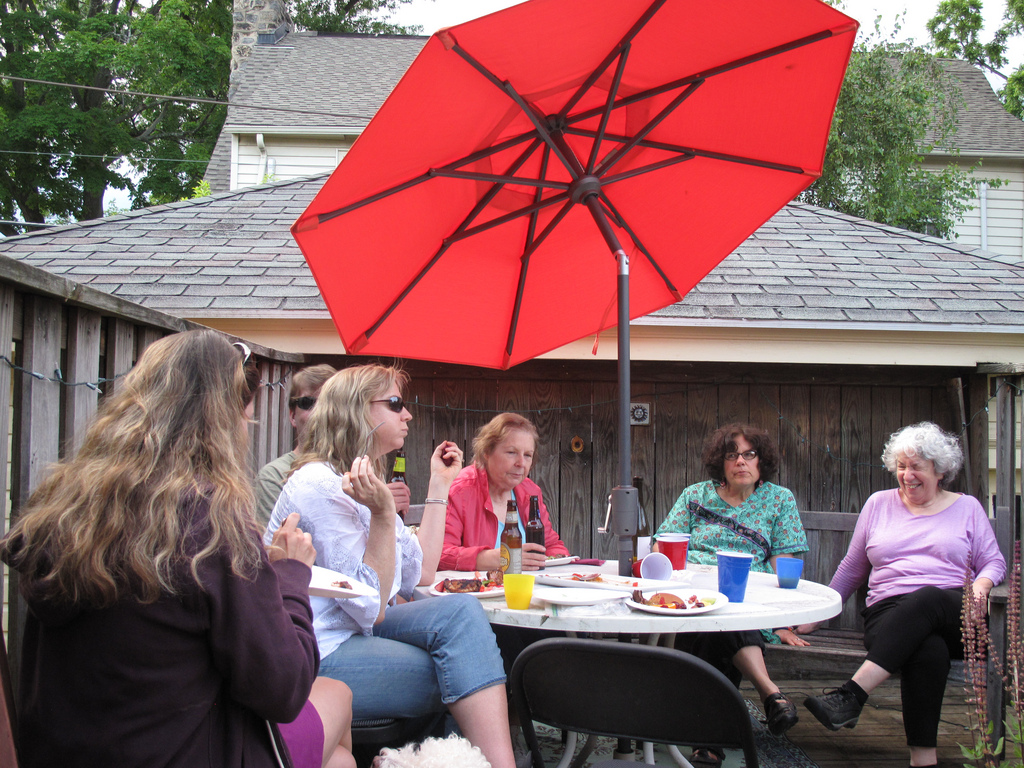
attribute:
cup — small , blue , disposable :
[705, 546, 776, 619]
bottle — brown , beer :
[366, 437, 421, 533]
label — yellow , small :
[381, 455, 420, 487]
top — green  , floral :
[647, 468, 813, 580]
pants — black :
[647, 614, 813, 700]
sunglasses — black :
[274, 370, 508, 440]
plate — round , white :
[620, 582, 732, 624]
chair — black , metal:
[515, 633, 757, 766]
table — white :
[391, 537, 864, 652]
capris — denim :
[296, 609, 526, 728]